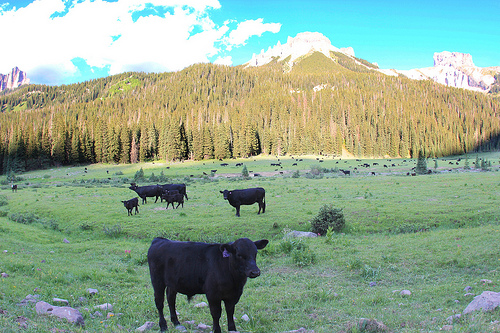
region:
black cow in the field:
[138, 224, 285, 326]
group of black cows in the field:
[115, 177, 282, 219]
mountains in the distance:
[118, 30, 498, 151]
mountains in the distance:
[0, 56, 30, 103]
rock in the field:
[453, 270, 498, 317]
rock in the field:
[454, 264, 493, 287]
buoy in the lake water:
[63, 49, 273, 143]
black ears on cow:
[211, 242, 240, 262]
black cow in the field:
[130, 219, 280, 311]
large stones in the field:
[438, 279, 495, 319]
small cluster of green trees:
[316, 218, 344, 249]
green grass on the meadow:
[351, 190, 461, 231]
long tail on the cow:
[252, 191, 275, 216]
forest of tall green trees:
[114, 75, 431, 159]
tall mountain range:
[211, 18, 396, 83]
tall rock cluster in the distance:
[4, 60, 33, 90]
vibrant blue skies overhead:
[345, 14, 432, 43]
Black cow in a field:
[146, 230, 246, 331]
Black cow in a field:
[213, 183, 272, 217]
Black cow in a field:
[117, 190, 148, 219]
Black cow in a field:
[158, 185, 184, 210]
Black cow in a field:
[124, 173, 156, 201]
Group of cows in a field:
[3, 144, 497, 324]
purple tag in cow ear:
[216, 245, 231, 257]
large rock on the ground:
[279, 220, 326, 251]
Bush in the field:
[308, 199, 349, 241]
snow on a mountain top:
[263, 20, 333, 65]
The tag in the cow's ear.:
[223, 248, 230, 257]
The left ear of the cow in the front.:
[220, 240, 230, 251]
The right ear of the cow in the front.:
[252, 240, 268, 249]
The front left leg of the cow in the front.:
[210, 294, 221, 329]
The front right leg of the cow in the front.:
[225, 301, 237, 331]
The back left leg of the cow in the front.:
[155, 289, 164, 326]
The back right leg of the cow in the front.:
[166, 291, 178, 324]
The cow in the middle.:
[218, 187, 272, 214]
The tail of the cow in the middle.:
[260, 189, 267, 214]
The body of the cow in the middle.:
[225, 187, 263, 205]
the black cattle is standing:
[146, 234, 268, 331]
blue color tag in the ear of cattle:
[149, 234, 269, 329]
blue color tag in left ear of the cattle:
[146, 236, 270, 331]